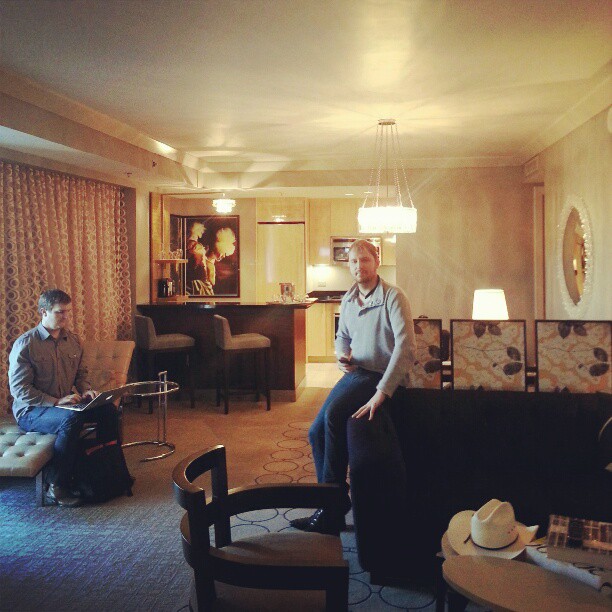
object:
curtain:
[0, 161, 133, 418]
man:
[289, 239, 416, 531]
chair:
[346, 388, 611, 584]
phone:
[339, 357, 364, 365]